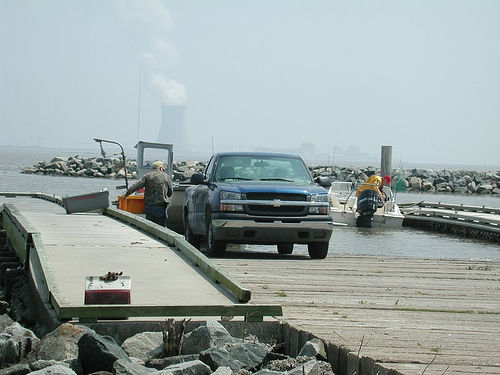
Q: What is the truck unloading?
A: Boat.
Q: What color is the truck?
A: Blue.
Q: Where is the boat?
A: Water.